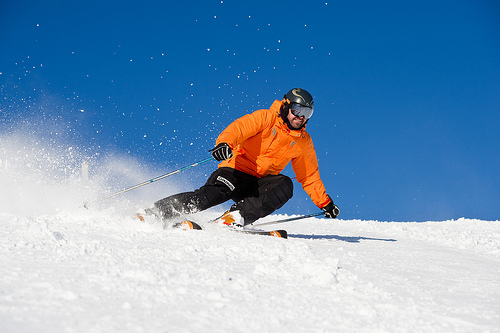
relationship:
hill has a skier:
[2, 209, 499, 332] [136, 87, 339, 226]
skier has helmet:
[136, 87, 339, 226] [284, 88, 315, 109]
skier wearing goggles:
[136, 87, 339, 226] [281, 95, 314, 120]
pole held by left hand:
[253, 209, 332, 229] [321, 202, 341, 219]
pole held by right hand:
[83, 154, 220, 212] [207, 142, 233, 160]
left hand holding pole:
[321, 202, 341, 219] [253, 209, 332, 229]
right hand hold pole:
[207, 142, 233, 160] [83, 154, 220, 212]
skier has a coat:
[136, 87, 339, 226] [215, 100, 333, 211]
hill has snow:
[2, 209, 499, 332] [4, 210, 496, 328]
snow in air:
[4, 101, 193, 193] [4, 9, 493, 215]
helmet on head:
[284, 88, 315, 109] [280, 87, 314, 131]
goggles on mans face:
[281, 95, 314, 120] [286, 109, 311, 129]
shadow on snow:
[286, 233, 400, 245] [4, 210, 496, 328]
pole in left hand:
[253, 209, 332, 229] [321, 202, 341, 219]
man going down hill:
[136, 87, 339, 226] [2, 209, 499, 332]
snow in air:
[4, 210, 496, 328] [4, 9, 493, 215]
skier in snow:
[136, 87, 339, 226] [4, 210, 496, 328]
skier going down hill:
[136, 87, 339, 226] [2, 209, 499, 332]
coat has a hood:
[215, 100, 333, 211] [270, 99, 284, 114]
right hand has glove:
[207, 142, 233, 160] [210, 142, 230, 161]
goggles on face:
[281, 95, 314, 120] [286, 109, 311, 129]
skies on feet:
[129, 214, 288, 239] [136, 209, 247, 230]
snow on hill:
[4, 210, 496, 328] [2, 209, 499, 332]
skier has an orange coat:
[136, 87, 339, 226] [215, 100, 333, 211]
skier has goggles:
[136, 87, 339, 226] [281, 95, 314, 120]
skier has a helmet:
[136, 87, 339, 226] [284, 88, 315, 109]